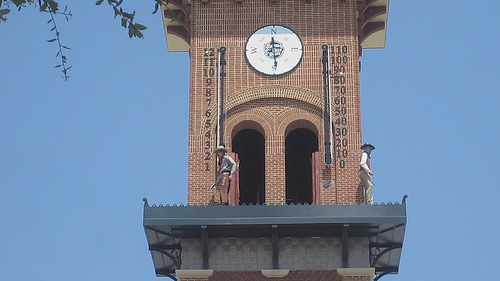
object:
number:
[202, 150, 214, 160]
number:
[201, 128, 212, 140]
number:
[203, 105, 215, 120]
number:
[201, 87, 216, 98]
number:
[204, 67, 215, 77]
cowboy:
[357, 142, 375, 204]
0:
[339, 161, 346, 170]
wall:
[198, 28, 308, 75]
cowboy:
[210, 144, 237, 204]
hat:
[212, 144, 226, 154]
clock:
[242, 25, 302, 77]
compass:
[269, 36, 276, 69]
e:
[290, 47, 298, 53]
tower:
[147, 0, 408, 281]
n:
[269, 27, 280, 36]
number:
[203, 161, 211, 173]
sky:
[2, 0, 499, 281]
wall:
[323, 37, 355, 57]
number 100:
[330, 55, 348, 64]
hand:
[270, 36, 277, 68]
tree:
[0, 0, 182, 81]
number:
[250, 29, 299, 72]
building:
[146, 0, 409, 281]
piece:
[40, 25, 79, 83]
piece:
[119, 18, 148, 40]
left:
[188, 41, 235, 207]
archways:
[226, 114, 324, 204]